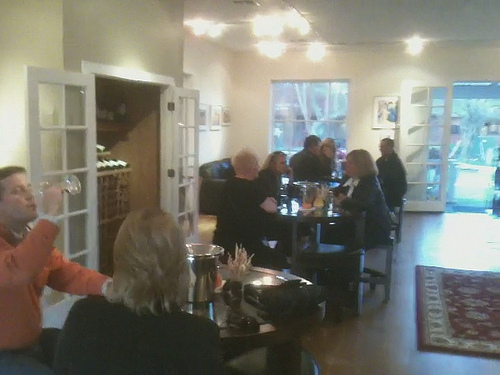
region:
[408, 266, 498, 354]
a large red area rug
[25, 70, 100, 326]
an open white door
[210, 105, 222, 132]
a wall picture frame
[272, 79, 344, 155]
a large window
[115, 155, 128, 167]
a wine bottle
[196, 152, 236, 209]
part of a leather couch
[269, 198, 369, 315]
a tall table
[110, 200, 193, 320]
the head of a woman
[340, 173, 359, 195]
part of a woman's white shirt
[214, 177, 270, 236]
a woman's black short sleeve shirt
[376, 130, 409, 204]
person sitting at table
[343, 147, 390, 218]
person sitting at table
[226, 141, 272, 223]
person sitting at table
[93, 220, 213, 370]
person sitting at table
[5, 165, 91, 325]
person sitting at table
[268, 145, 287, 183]
person sitting at table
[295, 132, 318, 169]
person sitting at table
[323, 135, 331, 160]
person sitting at table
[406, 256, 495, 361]
oriental rug on floor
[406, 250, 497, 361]
a burgundy white and gold carpet.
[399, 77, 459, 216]
a white door.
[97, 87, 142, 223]
a wine rack inside closet.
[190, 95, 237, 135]
three pictures on the wall.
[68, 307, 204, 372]
a woman is wearing a black jacket.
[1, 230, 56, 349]
a man is wearing a red shirt.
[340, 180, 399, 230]
a women is wearing a blue shirt.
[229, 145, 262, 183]
a women is wearing a short blonde hair style.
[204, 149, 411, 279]
a group of women talking at the table.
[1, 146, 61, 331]
a man is drinking wine.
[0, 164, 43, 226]
the head of a man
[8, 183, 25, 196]
the eye of a man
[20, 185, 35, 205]
the nose of a man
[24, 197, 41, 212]
the mouth of a man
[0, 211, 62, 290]
the arm of a man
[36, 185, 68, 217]
the hand of a man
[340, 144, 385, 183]
the head of a woman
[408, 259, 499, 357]
a rug on the floor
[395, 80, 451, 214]
a wood and glass door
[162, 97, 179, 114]
a hinge on the door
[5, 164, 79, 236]
a man drinking from a glass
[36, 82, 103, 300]
a french door in a restaurant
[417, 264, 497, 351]
a rug on the floor of a restaurant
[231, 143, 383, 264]
three people at a restaurant table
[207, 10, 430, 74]
ceiling light fixtures in a restaurant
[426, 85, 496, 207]
the back patio of a restaurant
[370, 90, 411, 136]
a painting on the wall of a restaurant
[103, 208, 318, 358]
the back of the head of a blond woman eating at a restaurant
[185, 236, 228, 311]
an ice bucket on a table at a restaurant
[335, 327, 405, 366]
a wooden floor in a restaurant